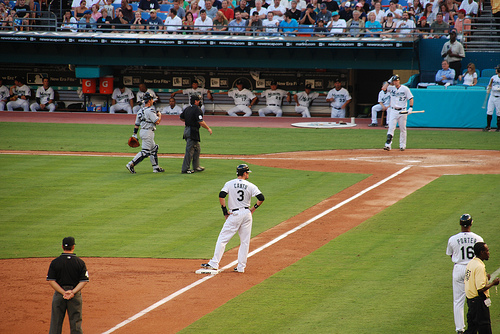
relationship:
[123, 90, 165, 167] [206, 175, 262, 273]
baseball player wears white